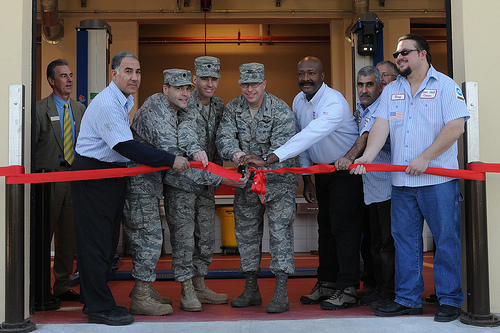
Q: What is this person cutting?
A: Red ribbon.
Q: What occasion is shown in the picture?
A: Opening ceremony.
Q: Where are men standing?
A: Behind the red ribbon.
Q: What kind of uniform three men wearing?
A: Military.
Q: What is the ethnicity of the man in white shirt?
A: African.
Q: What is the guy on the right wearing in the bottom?
A: A pair of blue jeans.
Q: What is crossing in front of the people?
A: Ribbon.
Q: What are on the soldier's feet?
A: Boots.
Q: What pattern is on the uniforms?
A: Camouflage.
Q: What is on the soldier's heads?
A: Hats.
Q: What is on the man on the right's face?
A: Sunglasses.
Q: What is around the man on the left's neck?
A: Tie.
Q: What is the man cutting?
A: Ribbon.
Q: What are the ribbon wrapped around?
A: Black poles.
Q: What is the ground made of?
A: Concrete.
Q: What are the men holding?
A: Ribbon.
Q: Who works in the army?
A: Three men in the middle.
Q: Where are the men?
A: In the building.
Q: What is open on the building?
A: Doors.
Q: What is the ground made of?
A: Concrete.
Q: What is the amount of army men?
A: Three.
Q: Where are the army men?
A: The middle.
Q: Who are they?
A: Army.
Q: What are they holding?
A: Ribbon.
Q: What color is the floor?
A: Red.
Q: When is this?
A: Daytime.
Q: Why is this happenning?
A: Grand opening.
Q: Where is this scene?
A: At a ribbon cutting.